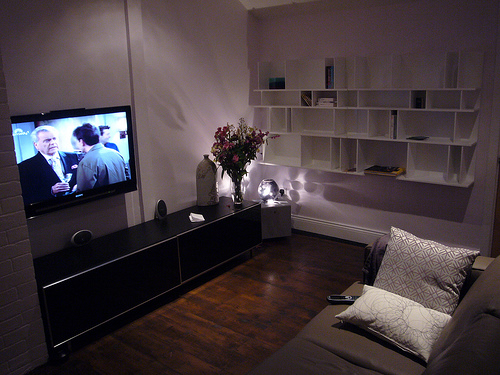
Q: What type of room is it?
A: It is a living room.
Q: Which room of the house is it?
A: It is a living room.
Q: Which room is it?
A: It is a living room.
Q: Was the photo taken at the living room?
A: Yes, it was taken in the living room.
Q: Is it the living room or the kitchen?
A: It is the living room.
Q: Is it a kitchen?
A: No, it is a living room.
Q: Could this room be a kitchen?
A: No, it is a living room.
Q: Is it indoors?
A: Yes, it is indoors.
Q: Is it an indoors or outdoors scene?
A: It is indoors.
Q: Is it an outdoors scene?
A: No, it is indoors.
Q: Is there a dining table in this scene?
A: No, there are no dining tables.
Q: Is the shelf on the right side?
A: Yes, the shelf is on the right of the image.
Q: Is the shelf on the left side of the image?
A: No, the shelf is on the right of the image.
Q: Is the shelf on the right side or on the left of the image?
A: The shelf is on the right of the image.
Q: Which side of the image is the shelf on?
A: The shelf is on the right of the image.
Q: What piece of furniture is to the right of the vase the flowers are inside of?
A: The piece of furniture is a shelf.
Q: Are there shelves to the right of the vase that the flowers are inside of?
A: Yes, there is a shelf to the right of the vase.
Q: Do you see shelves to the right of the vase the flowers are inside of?
A: Yes, there is a shelf to the right of the vase.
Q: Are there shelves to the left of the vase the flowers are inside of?
A: No, the shelf is to the right of the vase.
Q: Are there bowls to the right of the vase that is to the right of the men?
A: No, there is a shelf to the right of the vase.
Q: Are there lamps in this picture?
A: No, there are no lamps.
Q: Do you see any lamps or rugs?
A: No, there are no lamps or rugs.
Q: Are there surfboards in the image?
A: No, there are no surfboards.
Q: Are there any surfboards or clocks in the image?
A: No, there are no surfboards or clocks.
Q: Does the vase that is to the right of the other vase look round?
A: Yes, the vase is round.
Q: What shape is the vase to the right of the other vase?
A: The vase is round.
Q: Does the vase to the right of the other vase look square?
A: No, the vase is round.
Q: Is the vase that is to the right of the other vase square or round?
A: The vase is round.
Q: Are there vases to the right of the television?
A: Yes, there is a vase to the right of the television.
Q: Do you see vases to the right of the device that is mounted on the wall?
A: Yes, there is a vase to the right of the television.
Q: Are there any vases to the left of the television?
A: No, the vase is to the right of the television.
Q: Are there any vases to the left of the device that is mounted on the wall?
A: No, the vase is to the right of the television.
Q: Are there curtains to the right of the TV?
A: No, there is a vase to the right of the TV.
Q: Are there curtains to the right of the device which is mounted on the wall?
A: No, there is a vase to the right of the TV.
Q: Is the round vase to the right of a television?
A: Yes, the vase is to the right of a television.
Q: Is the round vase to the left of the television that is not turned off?
A: No, the vase is to the right of the television.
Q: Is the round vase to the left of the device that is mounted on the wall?
A: No, the vase is to the right of the television.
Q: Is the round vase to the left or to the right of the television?
A: The vase is to the right of the television.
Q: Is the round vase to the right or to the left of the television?
A: The vase is to the right of the television.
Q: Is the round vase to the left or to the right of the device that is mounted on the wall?
A: The vase is to the right of the television.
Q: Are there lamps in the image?
A: No, there are no lamps.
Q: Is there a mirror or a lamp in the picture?
A: No, there are no lamps or mirrors.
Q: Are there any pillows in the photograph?
A: Yes, there is a pillow.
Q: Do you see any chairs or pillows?
A: Yes, there is a pillow.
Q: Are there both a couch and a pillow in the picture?
A: Yes, there are both a pillow and a couch.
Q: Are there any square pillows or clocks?
A: Yes, there is a square pillow.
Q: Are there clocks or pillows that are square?
A: Yes, the pillow is square.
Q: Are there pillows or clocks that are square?
A: Yes, the pillow is square.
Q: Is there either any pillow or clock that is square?
A: Yes, the pillow is square.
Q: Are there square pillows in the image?
A: Yes, there is a square pillow.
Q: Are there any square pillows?
A: Yes, there is a square pillow.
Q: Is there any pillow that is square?
A: Yes, there is a pillow that is square.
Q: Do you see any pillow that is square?
A: Yes, there is a pillow that is square.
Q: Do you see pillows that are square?
A: Yes, there is a pillow that is square.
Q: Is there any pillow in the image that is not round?
A: Yes, there is a square pillow.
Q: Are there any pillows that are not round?
A: Yes, there is a square pillow.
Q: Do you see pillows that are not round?
A: Yes, there is a square pillow.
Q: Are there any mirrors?
A: No, there are no mirrors.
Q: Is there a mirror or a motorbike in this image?
A: No, there are no mirrors or motorcycles.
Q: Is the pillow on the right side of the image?
A: Yes, the pillow is on the right of the image.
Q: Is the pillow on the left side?
A: No, the pillow is on the right of the image.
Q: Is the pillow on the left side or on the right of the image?
A: The pillow is on the right of the image.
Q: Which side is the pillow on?
A: The pillow is on the right of the image.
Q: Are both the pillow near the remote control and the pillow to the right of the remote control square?
A: Yes, both the pillow and the pillow are square.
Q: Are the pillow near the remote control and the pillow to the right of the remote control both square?
A: Yes, both the pillow and the pillow are square.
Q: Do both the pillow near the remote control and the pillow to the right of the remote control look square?
A: Yes, both the pillow and the pillow are square.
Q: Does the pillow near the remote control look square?
A: Yes, the pillow is square.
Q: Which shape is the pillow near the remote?
A: The pillow is square.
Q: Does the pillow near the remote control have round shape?
A: No, the pillow is square.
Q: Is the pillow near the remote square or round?
A: The pillow is square.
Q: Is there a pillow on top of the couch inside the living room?
A: Yes, there is a pillow on top of the couch.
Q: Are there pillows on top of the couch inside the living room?
A: Yes, there is a pillow on top of the couch.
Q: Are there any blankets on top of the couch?
A: No, there is a pillow on top of the couch.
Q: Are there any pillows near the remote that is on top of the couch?
A: Yes, there is a pillow near the remote.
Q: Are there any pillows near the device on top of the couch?
A: Yes, there is a pillow near the remote.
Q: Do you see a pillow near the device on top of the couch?
A: Yes, there is a pillow near the remote.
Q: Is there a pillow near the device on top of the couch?
A: Yes, there is a pillow near the remote.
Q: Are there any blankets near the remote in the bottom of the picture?
A: No, there is a pillow near the remote.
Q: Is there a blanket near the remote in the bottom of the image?
A: No, there is a pillow near the remote.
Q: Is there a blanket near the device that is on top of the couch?
A: No, there is a pillow near the remote.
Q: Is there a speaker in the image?
A: Yes, there is a speaker.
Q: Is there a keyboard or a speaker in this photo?
A: Yes, there is a speaker.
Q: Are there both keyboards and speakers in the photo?
A: No, there is a speaker but no keyboards.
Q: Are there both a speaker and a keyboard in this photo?
A: No, there is a speaker but no keyboards.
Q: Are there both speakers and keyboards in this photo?
A: No, there is a speaker but no keyboards.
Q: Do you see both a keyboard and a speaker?
A: No, there is a speaker but no keyboards.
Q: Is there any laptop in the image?
A: No, there are no laptops.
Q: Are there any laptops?
A: No, there are no laptops.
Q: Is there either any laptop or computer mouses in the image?
A: No, there are no laptops or computer mousess.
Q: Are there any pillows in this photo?
A: Yes, there is a pillow.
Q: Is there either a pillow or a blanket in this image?
A: Yes, there is a pillow.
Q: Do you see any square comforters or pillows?
A: Yes, there is a square pillow.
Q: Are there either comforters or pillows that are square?
A: Yes, the pillow is square.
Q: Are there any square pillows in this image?
A: Yes, there is a square pillow.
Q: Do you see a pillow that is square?
A: Yes, there is a pillow that is square.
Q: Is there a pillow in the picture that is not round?
A: Yes, there is a square pillow.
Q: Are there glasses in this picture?
A: No, there are no glasses.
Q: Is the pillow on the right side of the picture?
A: Yes, the pillow is on the right of the image.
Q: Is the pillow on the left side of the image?
A: No, the pillow is on the right of the image.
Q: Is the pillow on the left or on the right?
A: The pillow is on the right of the image.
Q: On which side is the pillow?
A: The pillow is on the right of the image.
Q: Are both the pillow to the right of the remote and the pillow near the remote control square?
A: Yes, both the pillow and the pillow are square.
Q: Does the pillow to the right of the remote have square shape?
A: Yes, the pillow is square.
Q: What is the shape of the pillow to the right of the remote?
A: The pillow is square.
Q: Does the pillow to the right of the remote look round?
A: No, the pillow is square.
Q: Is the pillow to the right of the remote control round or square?
A: The pillow is square.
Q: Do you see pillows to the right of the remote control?
A: Yes, there is a pillow to the right of the remote control.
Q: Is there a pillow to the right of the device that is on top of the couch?
A: Yes, there is a pillow to the right of the remote control.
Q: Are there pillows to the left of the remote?
A: No, the pillow is to the right of the remote.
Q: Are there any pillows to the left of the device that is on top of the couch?
A: No, the pillow is to the right of the remote.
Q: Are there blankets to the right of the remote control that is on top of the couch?
A: No, there is a pillow to the right of the remote control.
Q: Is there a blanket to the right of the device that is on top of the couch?
A: No, there is a pillow to the right of the remote control.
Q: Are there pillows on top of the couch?
A: Yes, there is a pillow on top of the couch.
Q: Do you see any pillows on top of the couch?
A: Yes, there is a pillow on top of the couch.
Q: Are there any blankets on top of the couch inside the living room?
A: No, there is a pillow on top of the couch.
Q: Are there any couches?
A: Yes, there is a couch.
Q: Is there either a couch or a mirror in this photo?
A: Yes, there is a couch.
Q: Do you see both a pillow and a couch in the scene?
A: Yes, there are both a couch and a pillow.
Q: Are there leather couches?
A: Yes, there is a couch that is made of leather.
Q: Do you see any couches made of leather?
A: Yes, there is a couch that is made of leather.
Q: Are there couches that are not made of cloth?
A: Yes, there is a couch that is made of leather.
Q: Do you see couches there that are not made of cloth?
A: Yes, there is a couch that is made of leather.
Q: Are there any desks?
A: No, there are no desks.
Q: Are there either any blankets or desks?
A: No, there are no desks or blankets.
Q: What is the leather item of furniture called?
A: The piece of furniture is a couch.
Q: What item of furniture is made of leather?
A: The piece of furniture is a couch.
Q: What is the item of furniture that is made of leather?
A: The piece of furniture is a couch.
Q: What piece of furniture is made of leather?
A: The piece of furniture is a couch.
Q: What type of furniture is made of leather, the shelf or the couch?
A: The couch is made of leather.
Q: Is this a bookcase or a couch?
A: This is a couch.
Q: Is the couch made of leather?
A: Yes, the couch is made of leather.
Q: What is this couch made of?
A: The couch is made of leather.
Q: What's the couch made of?
A: The couch is made of leather.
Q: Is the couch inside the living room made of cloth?
A: No, the couch is made of leather.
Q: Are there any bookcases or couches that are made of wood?
A: No, there is a couch but it is made of leather.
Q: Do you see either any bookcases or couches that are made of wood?
A: No, there is a couch but it is made of leather.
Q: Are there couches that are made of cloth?
A: No, there is a couch but it is made of leather.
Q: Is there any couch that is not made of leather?
A: No, there is a couch but it is made of leather.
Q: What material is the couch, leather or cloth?
A: The couch is made of leather.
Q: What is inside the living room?
A: The couch is inside the living room.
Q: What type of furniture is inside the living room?
A: The piece of furniture is a couch.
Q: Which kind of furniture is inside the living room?
A: The piece of furniture is a couch.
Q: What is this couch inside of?
A: The couch is inside the living room.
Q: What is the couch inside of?
A: The couch is inside the living room.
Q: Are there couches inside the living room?
A: Yes, there is a couch inside the living room.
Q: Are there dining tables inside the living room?
A: No, there is a couch inside the living room.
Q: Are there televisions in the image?
A: Yes, there is a television.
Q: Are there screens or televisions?
A: Yes, there is a television.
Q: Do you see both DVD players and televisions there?
A: No, there is a television but no DVD players.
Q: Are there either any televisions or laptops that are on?
A: Yes, the television is on.